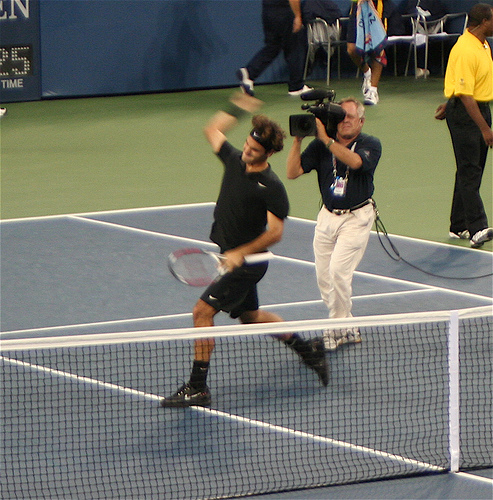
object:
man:
[158, 92, 328, 408]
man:
[286, 97, 380, 351]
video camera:
[290, 89, 344, 138]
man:
[434, 3, 491, 244]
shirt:
[445, 28, 492, 99]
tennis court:
[2, 200, 491, 499]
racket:
[167, 251, 277, 285]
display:
[0, 0, 43, 105]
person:
[237, 0, 315, 100]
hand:
[219, 248, 242, 273]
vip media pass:
[330, 176, 347, 196]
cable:
[374, 217, 492, 279]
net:
[0, 305, 490, 499]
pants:
[312, 198, 377, 329]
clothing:
[199, 139, 290, 317]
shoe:
[307, 336, 328, 385]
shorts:
[200, 251, 269, 319]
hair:
[250, 114, 286, 150]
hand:
[314, 117, 326, 140]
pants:
[445, 99, 492, 232]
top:
[0, 304, 492, 350]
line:
[69, 217, 429, 290]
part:
[2, 75, 491, 257]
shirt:
[209, 142, 287, 247]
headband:
[250, 127, 272, 148]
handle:
[242, 251, 274, 265]